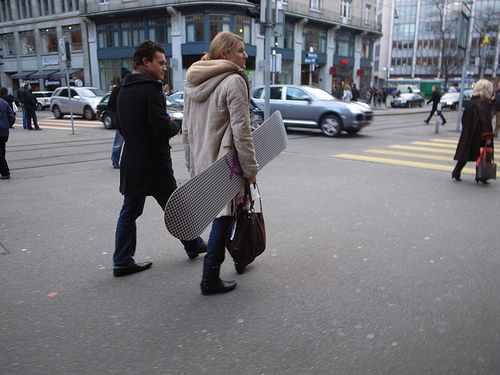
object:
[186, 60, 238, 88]
hood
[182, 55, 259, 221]
coat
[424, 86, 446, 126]
man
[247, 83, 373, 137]
car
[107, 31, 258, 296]
couple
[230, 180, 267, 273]
purse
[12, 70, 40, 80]
awnings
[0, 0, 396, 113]
building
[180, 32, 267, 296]
people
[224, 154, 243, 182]
x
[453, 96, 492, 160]
coat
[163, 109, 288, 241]
snowboard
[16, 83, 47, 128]
people waiting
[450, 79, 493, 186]
woman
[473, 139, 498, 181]
bags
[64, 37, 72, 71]
pole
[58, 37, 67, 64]
sign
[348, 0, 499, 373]
right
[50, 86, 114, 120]
cars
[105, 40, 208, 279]
man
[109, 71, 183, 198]
clothing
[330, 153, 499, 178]
lines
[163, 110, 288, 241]
board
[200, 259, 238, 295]
boots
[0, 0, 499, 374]
picture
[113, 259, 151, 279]
shoe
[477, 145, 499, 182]
brown bag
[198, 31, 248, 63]
hair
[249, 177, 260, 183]
hand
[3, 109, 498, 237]
intersection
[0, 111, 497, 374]
street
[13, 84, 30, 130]
people